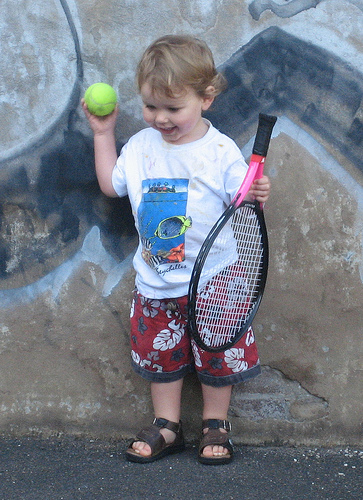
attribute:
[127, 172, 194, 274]
picture — fish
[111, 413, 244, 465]
sandles — brown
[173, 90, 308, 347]
racket — pink, black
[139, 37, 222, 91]
hair — blonde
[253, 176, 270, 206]
hand —  person's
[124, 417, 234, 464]
shoes — brown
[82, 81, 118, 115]
tennis ball — yellow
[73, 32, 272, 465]
boy — little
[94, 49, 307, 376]
boy — young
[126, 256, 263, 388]
shorts — floral, Hawaiian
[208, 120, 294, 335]
racket — black, pink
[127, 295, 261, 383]
shorts — floral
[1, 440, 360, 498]
ground — hard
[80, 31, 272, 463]
child — small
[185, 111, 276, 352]
racket — black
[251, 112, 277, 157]
handle — pink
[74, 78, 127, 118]
ball — tennis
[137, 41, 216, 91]
hair — blonde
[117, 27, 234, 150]
hair — blonde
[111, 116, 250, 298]
shirt — white